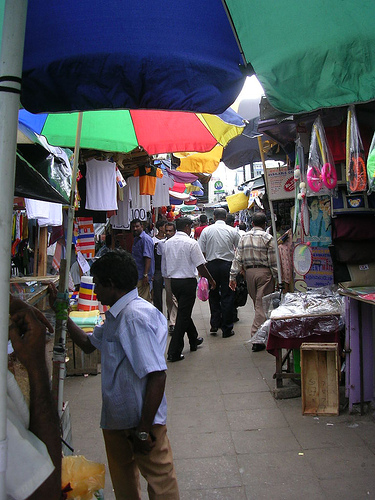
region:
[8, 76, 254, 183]
A colorful umbrella providing shade.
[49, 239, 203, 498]
A man in tan pants holding his arm up.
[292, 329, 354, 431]
A wooden box is sitting on its side.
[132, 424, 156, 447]
A silver wrist watch is on the arm of the man.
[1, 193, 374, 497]
A busy market place with several stands.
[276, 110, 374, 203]
Items in plastic bags are hanging.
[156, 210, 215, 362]
A man in a white shirt and black pants.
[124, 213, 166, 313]
A man in a blue shirt and tan pants.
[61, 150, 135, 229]
A white shirt is hanging.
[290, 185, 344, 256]
A poster with a woman in a blue shirt.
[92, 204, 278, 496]
People walking through the market place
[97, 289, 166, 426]
Man wearing light blue shirt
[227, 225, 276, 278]
Plaid shirt man is wearing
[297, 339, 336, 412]
Wood box cart standing on its side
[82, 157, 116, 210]
White shirt hanging from the ceiling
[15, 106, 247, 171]
Multi-colored canopy of the umbrella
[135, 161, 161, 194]
Orange shirt hanging from the ceiling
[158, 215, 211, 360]
Man walking through the market place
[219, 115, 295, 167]
Black canopy of the umbrella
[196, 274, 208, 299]
Pink bag full of items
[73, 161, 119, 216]
tshirt hanging on display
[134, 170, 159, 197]
tshirt hanging on display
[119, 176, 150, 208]
tshirt hanging on display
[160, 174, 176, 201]
tshirt hanging on display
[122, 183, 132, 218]
tshirt hanging on display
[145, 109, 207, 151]
panel on the umbrella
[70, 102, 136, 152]
panel on the umbrella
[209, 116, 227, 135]
panel on the umbrella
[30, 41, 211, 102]
panel on the umbrella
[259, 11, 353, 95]
panel on the umbrella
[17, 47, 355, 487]
busy market place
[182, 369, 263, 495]
square stone sidewalk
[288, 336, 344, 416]
wooden box set upright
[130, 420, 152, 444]
watch on a man's wrist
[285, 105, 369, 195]
hanging items for sale on display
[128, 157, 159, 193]
small tee-shirt for sale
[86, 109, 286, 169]
umbrellas open over the market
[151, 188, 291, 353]
crowd walks through the market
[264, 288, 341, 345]
table covered with plastic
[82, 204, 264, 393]
group of men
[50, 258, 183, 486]
man browsing stalls on street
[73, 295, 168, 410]
short sleeved blue shirt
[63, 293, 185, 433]
blue collared shirt on man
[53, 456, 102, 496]
yellow plastic bag in front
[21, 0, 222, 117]
blue fabric of umbrella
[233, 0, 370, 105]
green fabric of umbrella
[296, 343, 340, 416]
empty wooden crate on side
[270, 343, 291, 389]
wooden post of a table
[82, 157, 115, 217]
white shirt hanging down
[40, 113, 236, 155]
multi colored umbrella in area